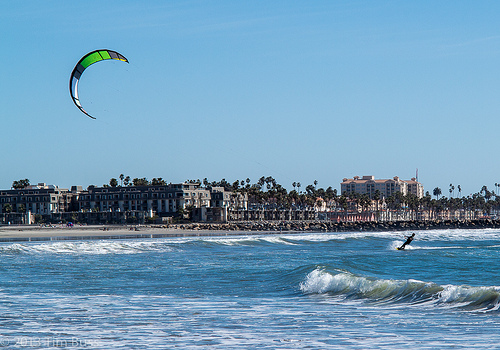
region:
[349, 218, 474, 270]
MAN PARA SAILING IN WATER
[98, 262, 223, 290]
BLUE WATER IN OCEAN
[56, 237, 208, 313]
WHITE FOAM IN WATER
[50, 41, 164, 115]
GREEN AREA ON SAIL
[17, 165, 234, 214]
APARTMENT BUILDINGS ON LAND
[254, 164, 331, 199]
TALL PALM TREES ON LAND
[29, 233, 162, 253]
SMOOTH SAND ON BEACH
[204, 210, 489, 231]
LARGE ROCKS ON SHORE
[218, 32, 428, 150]
CLEAR BLUE SKY ABOVE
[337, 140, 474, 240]
TALL BUILDING ON RIGHT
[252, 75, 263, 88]
A clear blue sky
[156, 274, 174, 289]
Small patch of the blue ocean water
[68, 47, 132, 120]
Wakeboard kite in the air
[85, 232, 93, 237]
Tiny patch of brown sand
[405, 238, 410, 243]
Black outfit of wakeboarder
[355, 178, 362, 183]
Light red roof of the building in the background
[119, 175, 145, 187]
A group of trees in the background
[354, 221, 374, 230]
Batch of rocks by the sand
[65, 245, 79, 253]
Small part of the white splash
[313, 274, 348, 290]
Medium section of a white wave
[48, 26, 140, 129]
Large kite in the air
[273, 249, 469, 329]
Small wave in the ocean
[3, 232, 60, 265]
Small wave in the ocean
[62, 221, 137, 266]
Small wave in the ocean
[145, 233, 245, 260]
Small wave in the ocean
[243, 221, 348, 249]
Small wave in the ocean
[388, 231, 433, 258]
Man in the ocean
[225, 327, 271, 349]
Small ripple in the ocean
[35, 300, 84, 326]
Small ripple in the ocean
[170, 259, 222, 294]
Small ripple in the ocean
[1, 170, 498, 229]
Beautiful City Off The Water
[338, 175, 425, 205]
Hotel Overlooking the ocean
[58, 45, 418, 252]
Man Surfing with a parachute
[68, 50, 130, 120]
Green And Blue Parachute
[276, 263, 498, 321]
Waves in the middle of the ocean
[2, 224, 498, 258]
Ocean Waves coming ashore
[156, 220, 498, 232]
Big Rock Shore Line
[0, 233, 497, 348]
Bright Blue Ocean Water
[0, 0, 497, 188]
Open Cloudless Sky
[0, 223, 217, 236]
Hot White Sandy Beach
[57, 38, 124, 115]
green para sail in air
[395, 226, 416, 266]
man para surfing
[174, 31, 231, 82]
white clouds in blue sky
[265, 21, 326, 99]
white clouds in blue sky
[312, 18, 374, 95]
white clouds in blue sky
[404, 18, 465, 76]
white clouds in blue sky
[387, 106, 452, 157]
white clouds in blue sky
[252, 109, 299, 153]
white clouds in blue sky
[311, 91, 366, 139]
white clouds in blue sky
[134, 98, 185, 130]
white clouds in blue sky